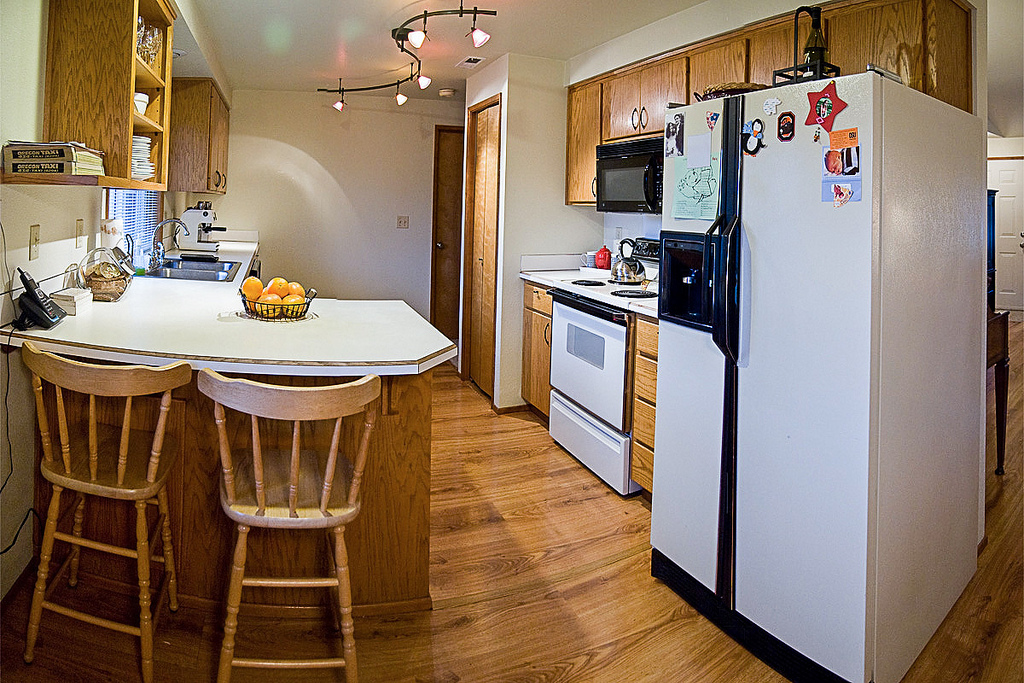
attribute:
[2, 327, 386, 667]
chairs — tall, wooden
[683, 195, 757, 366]
handles — black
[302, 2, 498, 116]
lights — on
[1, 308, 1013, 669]
floor — brown, wooden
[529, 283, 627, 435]
door — white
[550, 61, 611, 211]
cabinet — brown, wooden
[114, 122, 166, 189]
plates — stacked, white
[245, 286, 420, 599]
chair — wooden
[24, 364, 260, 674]
chair — wooden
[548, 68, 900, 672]
fridge — white and black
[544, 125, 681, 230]
microwave — black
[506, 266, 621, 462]
oven — white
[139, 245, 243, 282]
sink — double